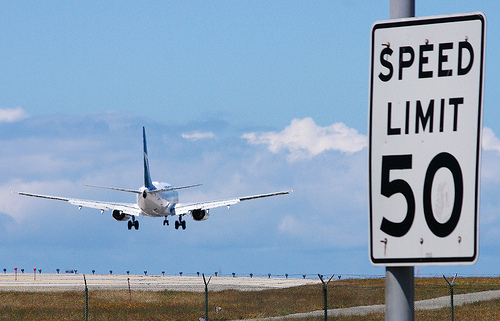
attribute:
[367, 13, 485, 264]
sign — white, rectangular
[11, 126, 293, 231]
plane — flying, white, blue, landing, lifting-off, metal, silver, reflective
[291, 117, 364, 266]
clouds — large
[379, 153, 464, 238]
number — black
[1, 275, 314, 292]
runway — tan, grey, cement, gray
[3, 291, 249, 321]
grass — brown, patchy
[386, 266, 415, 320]
pole — gray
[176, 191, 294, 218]
wing — dark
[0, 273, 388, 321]
fence — metal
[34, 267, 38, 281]
light — red